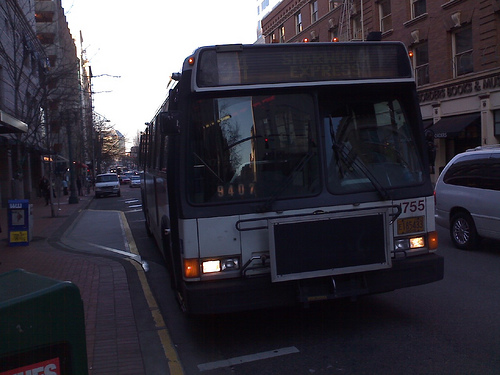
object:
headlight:
[199, 260, 226, 277]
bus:
[137, 40, 443, 307]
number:
[399, 200, 412, 218]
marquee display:
[189, 50, 411, 82]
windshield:
[190, 101, 424, 193]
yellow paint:
[112, 212, 173, 372]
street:
[119, 171, 499, 374]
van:
[95, 174, 120, 196]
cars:
[90, 170, 124, 201]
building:
[1, 0, 99, 214]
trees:
[32, 30, 87, 214]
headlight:
[403, 234, 427, 250]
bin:
[0, 265, 87, 375]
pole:
[61, 106, 80, 202]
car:
[126, 176, 138, 186]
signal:
[424, 233, 438, 247]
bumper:
[189, 256, 444, 307]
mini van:
[434, 147, 500, 242]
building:
[251, 0, 500, 93]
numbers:
[245, 184, 257, 202]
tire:
[451, 211, 474, 244]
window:
[152, 127, 174, 179]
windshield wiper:
[330, 128, 380, 193]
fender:
[183, 269, 454, 300]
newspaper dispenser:
[9, 200, 34, 243]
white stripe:
[189, 346, 316, 370]